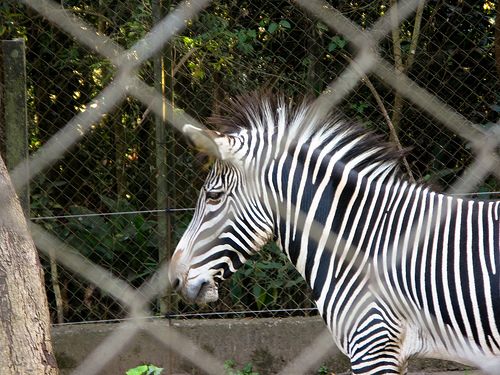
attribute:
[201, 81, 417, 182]
main — WHITE, BLACK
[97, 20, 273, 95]
leaves — green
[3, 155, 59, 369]
trunk — BROWN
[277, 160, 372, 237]
stripes — black, white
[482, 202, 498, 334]
stripe — black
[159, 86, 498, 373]
zebra — black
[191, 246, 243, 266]
stripe — black